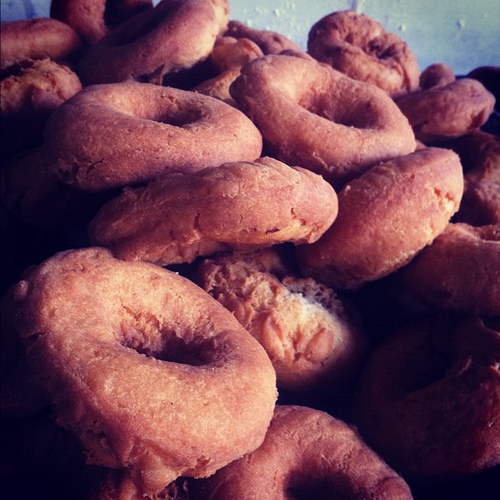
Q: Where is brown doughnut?
A: On other doughnuts.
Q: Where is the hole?
A: In doughnut.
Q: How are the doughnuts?
A: Piled.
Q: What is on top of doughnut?
A: Doughnut.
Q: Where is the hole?
A: In doughnut.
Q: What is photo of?
A: Donuts.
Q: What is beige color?
A: Donut.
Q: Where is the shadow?
A: Next to donut.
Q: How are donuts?
A: Side by side.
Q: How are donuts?
A: Next to each other.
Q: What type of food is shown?
A: Doughnuts.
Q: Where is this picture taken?
A: A bakery.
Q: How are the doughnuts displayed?
A: In a pile.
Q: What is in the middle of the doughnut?
A: A hole.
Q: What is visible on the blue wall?
A: Crumbs.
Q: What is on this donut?
A: Frosting.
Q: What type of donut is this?
A: Plain.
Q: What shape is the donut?
A: Round.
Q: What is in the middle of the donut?
A: Hole.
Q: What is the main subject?
A: Donuts.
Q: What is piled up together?
A: Donuts.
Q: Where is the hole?
A: Middle of donut.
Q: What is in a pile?
A: Donuts.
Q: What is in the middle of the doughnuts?
A: A hole.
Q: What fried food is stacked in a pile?
A: Doughnuts.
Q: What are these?
A: Doughnuts.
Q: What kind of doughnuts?
A: Plain.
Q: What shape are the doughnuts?
A: Round.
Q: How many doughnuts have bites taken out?
A: None.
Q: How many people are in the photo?
A: None.